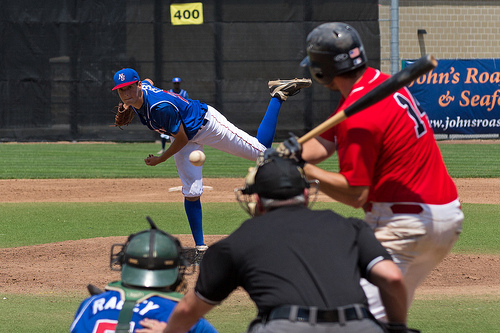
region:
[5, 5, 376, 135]
black mesh wall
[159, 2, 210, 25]
yellow number sign on wall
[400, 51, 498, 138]
blue, orange and white banner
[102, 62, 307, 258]
pitcher on baseball mound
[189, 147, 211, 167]
red and white baseball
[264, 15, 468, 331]
batter in red and white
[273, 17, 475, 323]
batter wearing black helmet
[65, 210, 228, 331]
catcher in blue and white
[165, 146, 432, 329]
umpire wearing black t-shirt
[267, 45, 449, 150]
black and tan bat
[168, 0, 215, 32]
400 is written in the photo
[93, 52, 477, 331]
people are playing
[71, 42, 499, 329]
5 people are in the photo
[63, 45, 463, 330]
people are wearing clothes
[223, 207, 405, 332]
the man is wearing a black shirt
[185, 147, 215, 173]
the baseball is white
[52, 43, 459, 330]
the people in the photo are men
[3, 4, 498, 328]
the photo was taken outdoors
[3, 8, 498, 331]
the photo was taken during the day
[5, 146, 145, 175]
the grass is green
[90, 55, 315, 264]
a lefty lets it fly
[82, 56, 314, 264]
it is a spinning pitch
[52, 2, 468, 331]
the batter is swinging at the pitch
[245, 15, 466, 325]
a batter who has opened his hips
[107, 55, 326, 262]
a lanky left handed pitcher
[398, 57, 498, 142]
a seafood restaurant ad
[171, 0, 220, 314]
400 feet to dead center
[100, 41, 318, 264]
pitcher with a stiff front leg who will hurt his shoulder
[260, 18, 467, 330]
a batter about to uncoil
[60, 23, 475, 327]
catcher set up on outside corner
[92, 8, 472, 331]
baseball game at stadium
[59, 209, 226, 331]
Catcher during an inning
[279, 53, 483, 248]
Batter swinging at ball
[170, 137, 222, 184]
baseball being thrown to the batter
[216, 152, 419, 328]
umpire watching the ball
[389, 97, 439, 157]
shirt had number fourteen written on the back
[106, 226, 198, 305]
the catcher's helmet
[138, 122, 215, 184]
the pitchers throwing arm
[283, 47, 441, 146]
bat used in baseball game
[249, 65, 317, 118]
pitcher is wearing nike cleats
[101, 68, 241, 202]
baseball player throwing a ball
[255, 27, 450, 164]
baseball player swinging a bat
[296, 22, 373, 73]
baseball player wearing a helmet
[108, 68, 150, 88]
the player is wearing a cap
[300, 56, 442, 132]
this is a baseball bat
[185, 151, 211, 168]
this is a baseball ball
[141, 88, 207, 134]
the player is wearing a blue costume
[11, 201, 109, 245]
the baseball pitch is green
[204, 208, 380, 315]
the ampire is wearing a black t shirt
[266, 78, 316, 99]
this is the players boots